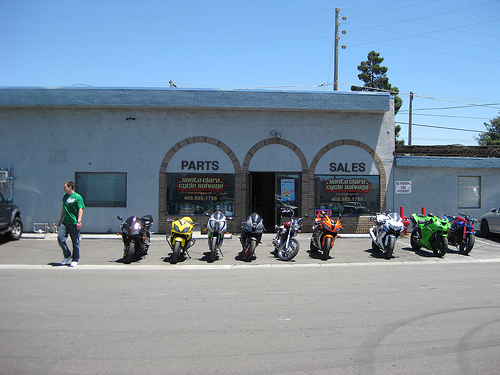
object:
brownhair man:
[56, 181, 86, 267]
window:
[315, 173, 380, 215]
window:
[166, 174, 235, 215]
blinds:
[458, 175, 481, 209]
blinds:
[75, 172, 128, 208]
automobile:
[478, 204, 499, 239]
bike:
[310, 210, 344, 259]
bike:
[166, 216, 198, 262]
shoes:
[60, 256, 77, 267]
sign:
[181, 160, 219, 170]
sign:
[174, 177, 226, 201]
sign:
[323, 177, 372, 201]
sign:
[395, 180, 413, 194]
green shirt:
[61, 192, 86, 225]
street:
[1, 235, 497, 374]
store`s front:
[1, 231, 500, 373]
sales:
[329, 162, 365, 172]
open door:
[246, 172, 276, 234]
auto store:
[0, 87, 500, 236]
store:
[0, 88, 394, 238]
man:
[57, 181, 86, 267]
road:
[0, 262, 500, 374]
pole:
[332, 7, 340, 92]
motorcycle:
[200, 210, 232, 260]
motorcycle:
[238, 210, 265, 262]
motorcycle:
[270, 198, 308, 262]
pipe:
[34, 222, 59, 234]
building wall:
[393, 157, 500, 234]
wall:
[393, 155, 500, 233]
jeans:
[57, 222, 80, 262]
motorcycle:
[115, 214, 154, 264]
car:
[1, 191, 24, 242]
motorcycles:
[114, 199, 479, 265]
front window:
[166, 174, 236, 216]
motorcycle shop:
[0, 87, 500, 232]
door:
[247, 171, 303, 233]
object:
[168, 80, 179, 88]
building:
[0, 86, 396, 234]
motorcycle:
[369, 200, 411, 265]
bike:
[410, 213, 452, 258]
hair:
[64, 181, 75, 190]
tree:
[351, 50, 404, 150]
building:
[0, 86, 499, 232]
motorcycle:
[442, 213, 481, 255]